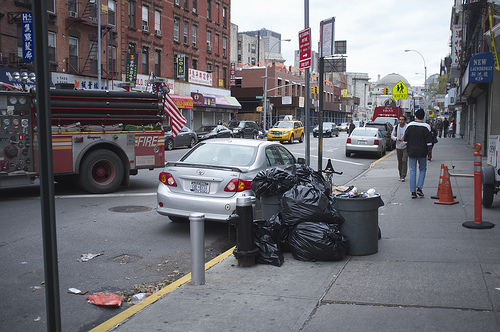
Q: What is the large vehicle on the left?
A: A fire truck.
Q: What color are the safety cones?
A: Orange.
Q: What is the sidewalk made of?
A: Concrete.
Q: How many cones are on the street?
A: Two.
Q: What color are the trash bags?
A: Black.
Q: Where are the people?
A: On the sidewalk.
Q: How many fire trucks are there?
A: One.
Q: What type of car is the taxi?
A: Suv.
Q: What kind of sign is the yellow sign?
A: Pedestrian.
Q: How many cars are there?
A: Eight.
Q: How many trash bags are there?
A: Six.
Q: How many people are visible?
A: Two.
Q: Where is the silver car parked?
A: Curb.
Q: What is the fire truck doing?
A: Reversing.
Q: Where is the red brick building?
A: Left.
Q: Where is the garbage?
A: Curb.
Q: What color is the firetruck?
A: Red.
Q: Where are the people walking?
A: Sidewalk.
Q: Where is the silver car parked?
A: Beside trash.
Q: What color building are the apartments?
A: Red.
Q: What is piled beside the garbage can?
A: Trash bags.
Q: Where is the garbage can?
A: On the curb.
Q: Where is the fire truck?
A: In the street.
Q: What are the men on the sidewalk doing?
A: Walking.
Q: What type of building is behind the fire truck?
A: Brick.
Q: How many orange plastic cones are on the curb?
A: Two.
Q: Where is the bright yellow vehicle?
A: In the street.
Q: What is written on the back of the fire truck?
A: Fire.